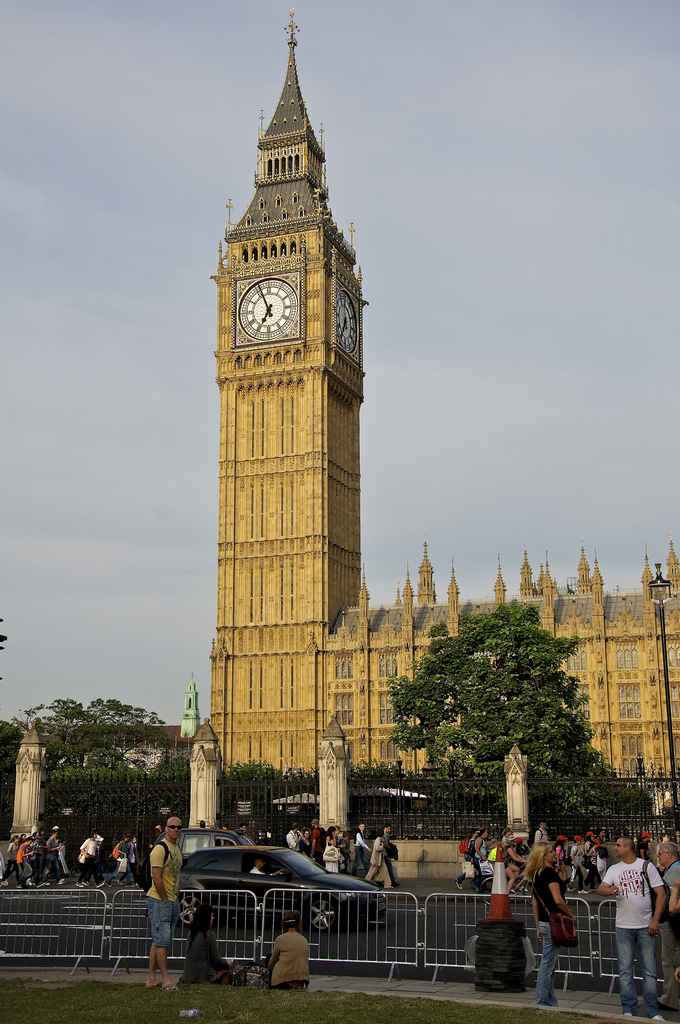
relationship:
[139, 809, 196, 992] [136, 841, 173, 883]
man carrying backpack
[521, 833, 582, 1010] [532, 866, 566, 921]
woman wearing shirt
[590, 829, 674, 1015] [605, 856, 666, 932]
man wearing t-shirt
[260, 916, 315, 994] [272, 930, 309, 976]
man wearing jacket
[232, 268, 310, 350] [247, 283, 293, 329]
clock has dials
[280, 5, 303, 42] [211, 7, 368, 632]
weather vane on top of tower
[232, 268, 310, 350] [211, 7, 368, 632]
clock on tower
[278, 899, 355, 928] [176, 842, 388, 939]
front tire on car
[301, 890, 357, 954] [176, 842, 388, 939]
back tire on car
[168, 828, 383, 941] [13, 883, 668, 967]
car on road